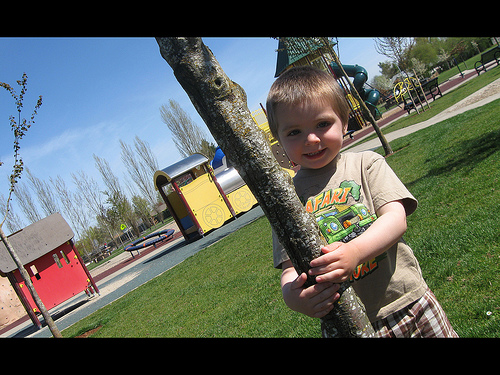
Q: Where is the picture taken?
A: Park.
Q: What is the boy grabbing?
A: A tree.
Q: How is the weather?
A: Mostly clear.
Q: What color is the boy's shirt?
A: Brown.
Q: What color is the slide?
A: Green.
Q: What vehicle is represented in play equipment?
A: Train.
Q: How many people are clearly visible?
A: 1.